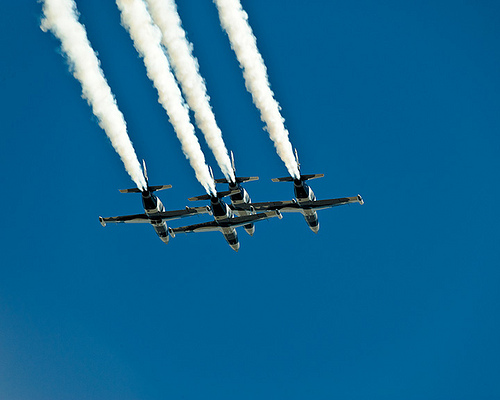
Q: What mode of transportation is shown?
A: Jets.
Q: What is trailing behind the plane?
A: Smoke.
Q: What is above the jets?
A: Sky.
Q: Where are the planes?
A: In the sky.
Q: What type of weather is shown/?
A: Clear.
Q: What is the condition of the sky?
A: Clear and blue.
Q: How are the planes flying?
A: In formation.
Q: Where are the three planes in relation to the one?
A: The three is flying above the plane.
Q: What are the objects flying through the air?
A: Planes.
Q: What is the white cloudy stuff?
A: Condensation.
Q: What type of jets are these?
A: Military.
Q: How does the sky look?
A: Clear and blue.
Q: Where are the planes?
A: In the sky.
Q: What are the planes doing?
A: Flying.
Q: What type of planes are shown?
A: Jets.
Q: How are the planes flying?
A: In formation.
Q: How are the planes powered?
A: Jet engines.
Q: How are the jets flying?
A: In formation.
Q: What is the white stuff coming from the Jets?
A: Vapor trails.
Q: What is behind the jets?
A: The sky.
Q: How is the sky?
A: Clear blue.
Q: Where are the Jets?
A: In the sky.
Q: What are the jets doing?
A: Flying.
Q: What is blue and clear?
A: The sky.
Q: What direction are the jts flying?
A: Away from the camera.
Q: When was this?
A: Daytime.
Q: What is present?
A: Planes.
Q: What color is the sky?
A: Blue.